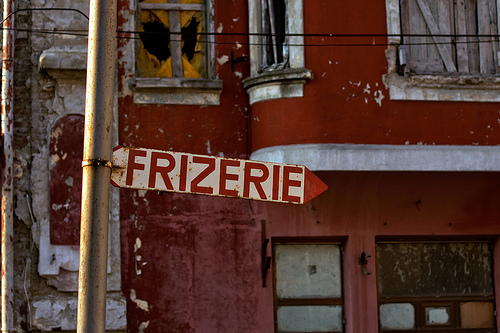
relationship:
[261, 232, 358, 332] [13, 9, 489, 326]
door of house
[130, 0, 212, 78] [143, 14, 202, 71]
window of curtains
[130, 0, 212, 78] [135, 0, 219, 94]
window of wood frame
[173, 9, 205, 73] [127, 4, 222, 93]
polythene material of window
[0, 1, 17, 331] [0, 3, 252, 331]
pipe in wall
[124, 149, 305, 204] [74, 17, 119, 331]
letters in pole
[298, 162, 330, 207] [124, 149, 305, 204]
point in letters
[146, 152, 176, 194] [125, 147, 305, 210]
letter in sign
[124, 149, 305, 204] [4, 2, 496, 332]
letters in building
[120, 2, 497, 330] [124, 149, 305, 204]
concrete wall in letters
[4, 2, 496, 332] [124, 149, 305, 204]
building behind letters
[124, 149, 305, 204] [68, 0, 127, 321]
letters on pole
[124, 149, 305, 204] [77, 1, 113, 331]
letters on pole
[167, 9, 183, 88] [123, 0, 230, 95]
wood on window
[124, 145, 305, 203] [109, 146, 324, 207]
letters on sign